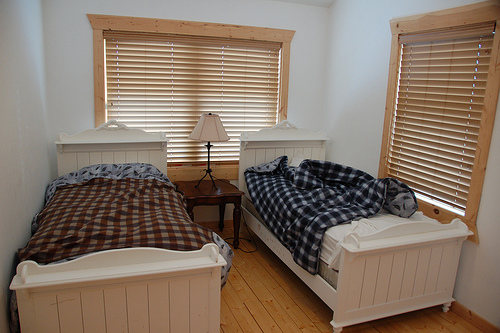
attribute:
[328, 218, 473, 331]
foot board — white